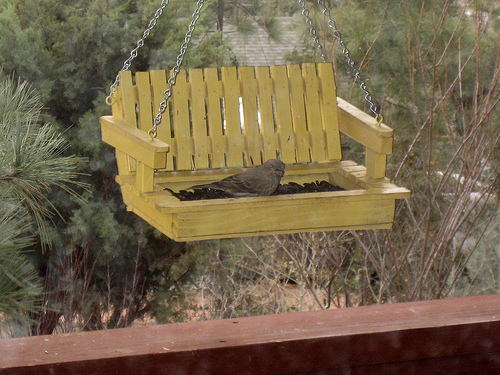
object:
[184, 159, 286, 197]
bird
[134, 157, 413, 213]
seat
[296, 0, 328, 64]
chain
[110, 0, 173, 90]
chain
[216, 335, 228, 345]
hole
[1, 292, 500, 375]
wood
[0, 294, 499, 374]
rail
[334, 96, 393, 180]
armrest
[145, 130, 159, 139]
hook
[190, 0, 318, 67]
roof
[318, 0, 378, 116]
chain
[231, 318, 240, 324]
hole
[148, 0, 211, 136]
chains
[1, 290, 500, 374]
wall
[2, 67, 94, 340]
bough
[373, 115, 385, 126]
eye hook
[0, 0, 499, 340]
backyard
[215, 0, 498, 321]
branches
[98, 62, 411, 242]
bench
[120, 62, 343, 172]
back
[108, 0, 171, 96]
metal chain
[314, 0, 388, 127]
metal chain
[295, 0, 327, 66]
metal chain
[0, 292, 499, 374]
painted board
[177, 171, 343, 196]
bird food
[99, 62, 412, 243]
bird feeder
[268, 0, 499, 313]
bush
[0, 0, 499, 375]
area